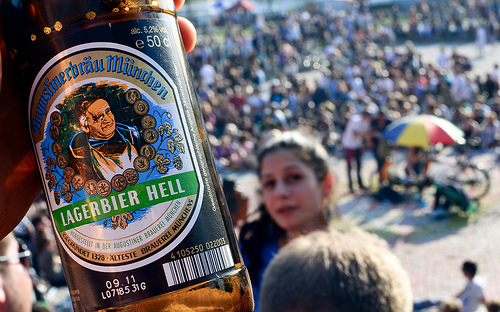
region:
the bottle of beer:
[1, 0, 251, 310]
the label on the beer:
[15, 17, 235, 305]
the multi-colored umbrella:
[382, 114, 464, 146]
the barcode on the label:
[163, 243, 234, 286]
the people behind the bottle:
[2, 0, 499, 310]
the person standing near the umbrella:
[343, 103, 378, 193]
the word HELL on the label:
[146, 177, 183, 200]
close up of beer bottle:
[31, 1, 256, 310]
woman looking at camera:
[258, 127, 338, 237]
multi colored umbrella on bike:
[377, 110, 492, 204]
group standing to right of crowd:
[391, 0, 495, 42]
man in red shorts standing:
[339, 109, 378, 196]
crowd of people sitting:
[207, 66, 331, 132]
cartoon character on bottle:
[64, 91, 140, 173]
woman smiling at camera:
[250, 124, 342, 239]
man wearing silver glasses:
[0, 234, 38, 290]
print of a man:
[69, 95, 139, 182]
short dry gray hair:
[260, 223, 415, 310]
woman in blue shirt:
[234, 131, 340, 310]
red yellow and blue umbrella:
[385, 114, 467, 150]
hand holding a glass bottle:
[1, 0, 256, 311]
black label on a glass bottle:
[20, 13, 240, 309]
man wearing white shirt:
[337, 106, 372, 196]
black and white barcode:
[161, 240, 236, 286]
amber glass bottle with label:
[16, 1, 256, 310]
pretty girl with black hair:
[238, 130, 333, 290]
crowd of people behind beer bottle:
[182, 2, 498, 169]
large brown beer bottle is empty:
[7, 0, 256, 310]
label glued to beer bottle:
[11, 14, 245, 310]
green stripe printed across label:
[51, 169, 199, 232]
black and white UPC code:
[159, 244, 234, 286]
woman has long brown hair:
[235, 131, 345, 309]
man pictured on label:
[70, 98, 137, 177]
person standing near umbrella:
[339, 107, 370, 184]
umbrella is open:
[382, 113, 464, 151]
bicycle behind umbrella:
[392, 148, 488, 200]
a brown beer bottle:
[1, 7, 263, 306]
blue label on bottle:
[14, 7, 274, 309]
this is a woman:
[212, 96, 356, 253]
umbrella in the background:
[366, 70, 495, 206]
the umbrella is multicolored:
[351, 87, 486, 176]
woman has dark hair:
[251, 105, 345, 187]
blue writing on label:
[18, 44, 183, 147]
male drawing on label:
[44, 85, 167, 201]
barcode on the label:
[152, 235, 252, 301]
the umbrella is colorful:
[391, 110, 468, 150]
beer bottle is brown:
[30, 12, 275, 310]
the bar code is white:
[162, 244, 232, 286]